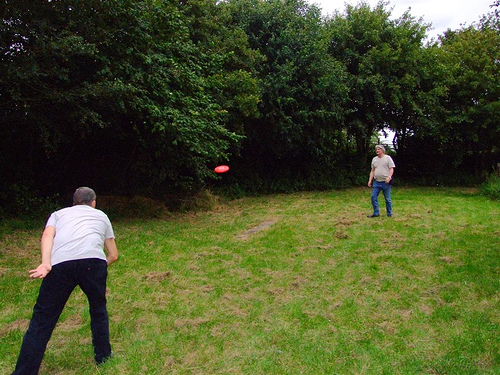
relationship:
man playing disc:
[366, 141, 396, 218] [214, 165, 230, 174]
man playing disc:
[11, 186, 118, 375] [214, 165, 230, 174]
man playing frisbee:
[366, 145, 396, 218] [202, 156, 242, 178]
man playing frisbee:
[11, 186, 118, 375] [202, 156, 242, 178]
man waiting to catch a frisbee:
[366, 145, 396, 218] [210, 162, 233, 174]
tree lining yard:
[318, 0, 431, 182] [6, 190, 499, 368]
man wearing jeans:
[366, 145, 396, 218] [371, 180, 395, 220]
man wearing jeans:
[366, 145, 396, 218] [359, 176, 416, 210]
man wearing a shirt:
[11, 186, 118, 375] [36, 201, 118, 271]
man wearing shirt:
[366, 145, 396, 218] [32, 200, 139, 277]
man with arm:
[11, 186, 118, 375] [36, 225, 53, 264]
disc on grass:
[214, 165, 230, 174] [9, 165, 479, 357]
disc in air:
[214, 165, 230, 174] [314, 0, 480, 25]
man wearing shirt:
[366, 145, 396, 218] [364, 151, 399, 186]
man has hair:
[366, 145, 396, 218] [372, 142, 386, 149]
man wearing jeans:
[4, 178, 137, 368] [12, 261, 137, 366]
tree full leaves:
[318, 0, 431, 182] [5, 3, 476, 207]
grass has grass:
[34, 196, 479, 360] [0, 196, 500, 375]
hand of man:
[29, 252, 56, 282] [11, 186, 118, 375]